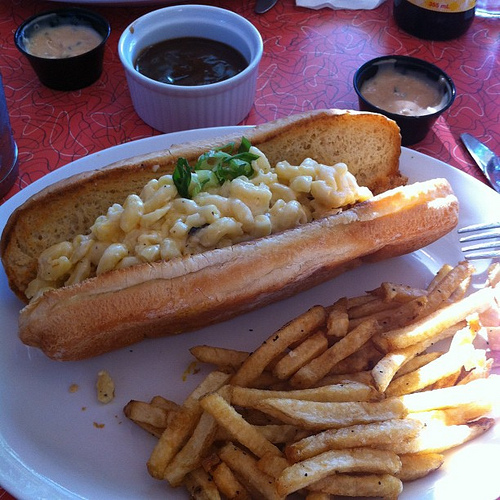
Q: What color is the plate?
A: White.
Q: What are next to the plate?
A: Sauce.